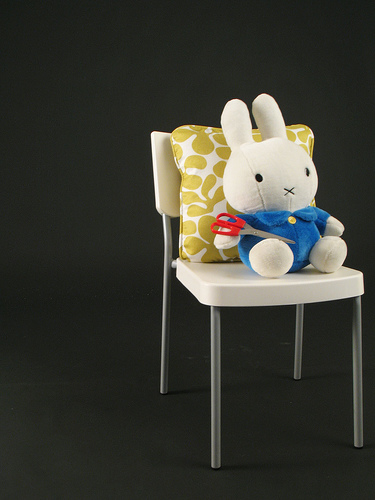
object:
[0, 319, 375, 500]
floor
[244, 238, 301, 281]
foot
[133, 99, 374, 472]
chair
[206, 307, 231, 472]
chair leg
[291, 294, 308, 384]
chair leg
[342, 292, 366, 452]
chair leg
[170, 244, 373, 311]
seat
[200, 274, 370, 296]
edge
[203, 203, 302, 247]
scissors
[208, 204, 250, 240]
handle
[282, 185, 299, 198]
nose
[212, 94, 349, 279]
teddy bear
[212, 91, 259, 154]
ears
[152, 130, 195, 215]
back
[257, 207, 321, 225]
tie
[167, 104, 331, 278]
pillow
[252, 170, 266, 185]
eyes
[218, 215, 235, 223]
holes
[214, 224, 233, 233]
holes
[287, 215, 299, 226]
button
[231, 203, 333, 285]
clothes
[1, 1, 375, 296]
wall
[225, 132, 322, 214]
face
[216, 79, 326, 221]
head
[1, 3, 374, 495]
room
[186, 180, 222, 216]
flower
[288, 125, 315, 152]
flower